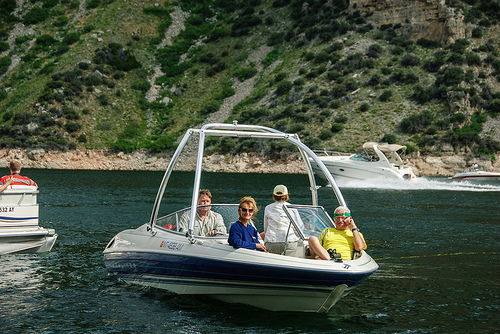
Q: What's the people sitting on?
A: Boat.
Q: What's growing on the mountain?
A: Foliage.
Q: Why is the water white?
A: It's splashing.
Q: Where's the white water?
A: Under boat.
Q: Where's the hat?
A: On head.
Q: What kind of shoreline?
A: Rocky.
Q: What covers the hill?
A: Vegetation.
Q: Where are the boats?
A: Water.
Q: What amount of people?
A: Four.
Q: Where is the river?
A: Foothills.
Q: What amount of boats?
A: Four.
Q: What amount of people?
A: Four.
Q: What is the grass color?
A: Green.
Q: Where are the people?
A: Boat.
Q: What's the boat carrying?
A: The people.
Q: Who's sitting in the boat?
A: The people.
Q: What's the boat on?
A: The water.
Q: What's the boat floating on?
A: Water.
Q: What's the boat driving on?
A: The water.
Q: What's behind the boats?
A: Mountain.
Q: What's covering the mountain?
A: Foliage.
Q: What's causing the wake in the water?
A: Boat.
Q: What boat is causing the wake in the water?
A: Boat near mountain.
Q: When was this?
A: Daytime.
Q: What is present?
A: Boats.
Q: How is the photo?
A: Clear.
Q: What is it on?
A: Water.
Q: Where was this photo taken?
A: In a lake.